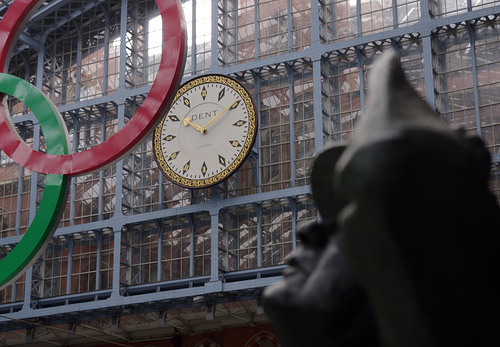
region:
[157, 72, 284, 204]
clock is black and gold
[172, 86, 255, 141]
clock hands are gold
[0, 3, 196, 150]
the ring is red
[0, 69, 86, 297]
the ring is green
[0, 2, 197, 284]
the rings are circular shaped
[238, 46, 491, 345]
the statue is brown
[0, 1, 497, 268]
building made of glass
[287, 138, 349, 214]
statue wearing a hat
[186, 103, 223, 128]
word dent on the clock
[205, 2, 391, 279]
structure's color is gray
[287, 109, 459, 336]
a black stone statue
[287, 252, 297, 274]
lips on the face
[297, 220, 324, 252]
nose on the statue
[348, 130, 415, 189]
elbow of the statue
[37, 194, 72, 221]
green ring on the wall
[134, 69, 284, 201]
a fancy analog clock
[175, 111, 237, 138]
golden hands on clock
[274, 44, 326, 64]
gray metal support beam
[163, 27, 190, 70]
red ring hanging on the wall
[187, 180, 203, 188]
gold floral design on the clock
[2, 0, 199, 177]
A huge red circle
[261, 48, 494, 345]
A statute of a man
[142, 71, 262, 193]
A gold, whitem and black clock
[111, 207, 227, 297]
A part of a lot of windows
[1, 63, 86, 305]
A big green ring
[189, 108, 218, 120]
The word Dent on a clock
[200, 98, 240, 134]
The minute hand on a clock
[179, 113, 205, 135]
The hour hand on a clock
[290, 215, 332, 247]
The nose on a statute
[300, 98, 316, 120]
A single window pane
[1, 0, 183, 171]
A large red circle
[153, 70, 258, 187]
A large round clock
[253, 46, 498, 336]
A statue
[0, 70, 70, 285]
A large green circle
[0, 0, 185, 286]
The edge of the olympic symbol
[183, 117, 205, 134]
hour hand on the clock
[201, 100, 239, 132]
minute hand on the clock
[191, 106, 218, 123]
Branding on the clock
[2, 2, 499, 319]
A large set of windows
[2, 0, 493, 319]
Large metal support beams behind the windows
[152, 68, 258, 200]
Clock on the wall.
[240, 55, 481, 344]
Statute in front of the camera.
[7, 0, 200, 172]
Red circle on the wall.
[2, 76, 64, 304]
Half of a green circle.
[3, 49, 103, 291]
The circles are connected.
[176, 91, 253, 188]
The clock is in Roman Numerals.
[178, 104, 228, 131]
Dent on the clock.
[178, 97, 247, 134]
The hands are gold.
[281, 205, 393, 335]
Face on the statute.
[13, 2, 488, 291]
Blue bars in the building.